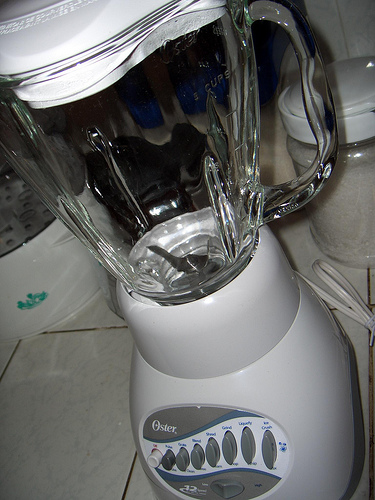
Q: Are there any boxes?
A: No, there are no boxes.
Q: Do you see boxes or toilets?
A: No, there are no boxes or toilets.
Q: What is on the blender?
A: The wire is on the blender.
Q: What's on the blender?
A: The wire is on the blender.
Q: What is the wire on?
A: The wire is on the blender.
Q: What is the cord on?
A: The wire is on the blender.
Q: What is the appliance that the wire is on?
A: The appliance is a blender.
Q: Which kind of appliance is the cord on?
A: The wire is on the blender.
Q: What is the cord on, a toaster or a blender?
A: The cord is on a blender.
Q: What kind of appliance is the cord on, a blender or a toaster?
A: The cord is on a blender.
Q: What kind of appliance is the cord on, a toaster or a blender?
A: The cord is on a blender.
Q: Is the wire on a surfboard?
A: No, the wire is on the blender.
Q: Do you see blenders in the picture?
A: Yes, there is a blender.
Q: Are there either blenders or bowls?
A: Yes, there is a blender.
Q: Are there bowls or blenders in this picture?
A: Yes, there is a blender.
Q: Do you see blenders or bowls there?
A: Yes, there is a blender.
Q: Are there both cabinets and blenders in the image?
A: No, there is a blender but no cabinets.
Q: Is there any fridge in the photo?
A: No, there are no refrigerators.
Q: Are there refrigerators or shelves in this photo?
A: No, there are no refrigerators or shelves.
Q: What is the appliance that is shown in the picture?
A: The appliance is a blender.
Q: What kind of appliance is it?
A: The appliance is a blender.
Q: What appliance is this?
A: This is a blender.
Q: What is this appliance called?
A: This is a blender.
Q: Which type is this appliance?
A: This is a blender.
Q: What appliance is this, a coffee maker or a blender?
A: This is a blender.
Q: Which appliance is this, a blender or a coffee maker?
A: This is a blender.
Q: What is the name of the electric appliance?
A: The appliance is a blender.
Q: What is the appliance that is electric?
A: The appliance is a blender.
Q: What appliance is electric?
A: The appliance is a blender.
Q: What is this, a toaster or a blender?
A: This is a blender.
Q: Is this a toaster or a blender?
A: This is a blender.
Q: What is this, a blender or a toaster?
A: This is a blender.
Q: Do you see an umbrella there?
A: No, there are no umbrellas.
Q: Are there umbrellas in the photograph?
A: No, there are no umbrellas.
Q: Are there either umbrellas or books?
A: No, there are no umbrellas or books.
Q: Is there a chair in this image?
A: Yes, there is a chair.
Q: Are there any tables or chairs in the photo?
A: Yes, there is a chair.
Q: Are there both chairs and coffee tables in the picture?
A: No, there is a chair but no coffee tables.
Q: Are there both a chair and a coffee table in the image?
A: No, there is a chair but no coffee tables.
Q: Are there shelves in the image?
A: No, there are no shelves.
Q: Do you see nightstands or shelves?
A: No, there are no shelves or nightstands.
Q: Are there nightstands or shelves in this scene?
A: No, there are no shelves or nightstands.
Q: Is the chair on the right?
A: Yes, the chair is on the right of the image.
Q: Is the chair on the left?
A: No, the chair is on the right of the image.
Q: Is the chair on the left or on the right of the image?
A: The chair is on the right of the image.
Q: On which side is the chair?
A: The chair is on the right of the image.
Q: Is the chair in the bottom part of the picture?
A: Yes, the chair is in the bottom of the image.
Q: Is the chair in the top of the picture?
A: No, the chair is in the bottom of the image.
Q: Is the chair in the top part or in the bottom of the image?
A: The chair is in the bottom of the image.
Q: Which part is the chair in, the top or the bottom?
A: The chair is in the bottom of the image.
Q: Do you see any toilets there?
A: No, there are no toilets.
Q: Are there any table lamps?
A: No, there are no table lamps.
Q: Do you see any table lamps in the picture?
A: No, there are no table lamps.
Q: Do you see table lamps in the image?
A: No, there are no table lamps.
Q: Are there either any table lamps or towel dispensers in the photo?
A: No, there are no table lamps or towel dispensers.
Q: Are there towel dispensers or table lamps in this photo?
A: No, there are no table lamps or towel dispensers.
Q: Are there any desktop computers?
A: No, there are no desktop computers.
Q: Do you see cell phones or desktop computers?
A: No, there are no desktop computers or cell phones.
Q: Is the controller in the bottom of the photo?
A: Yes, the controller is in the bottom of the image.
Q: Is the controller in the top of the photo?
A: No, the controller is in the bottom of the image.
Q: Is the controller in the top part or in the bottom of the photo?
A: The controller is in the bottom of the image.